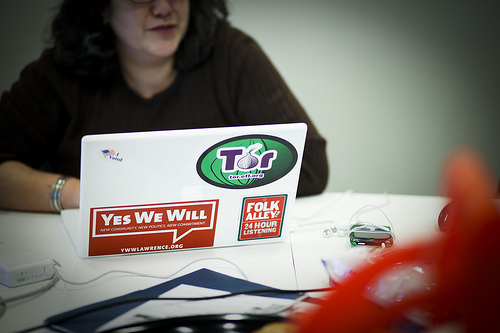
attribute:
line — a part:
[235, 197, 246, 241]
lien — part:
[341, 195, 397, 221]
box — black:
[349, 229, 393, 247]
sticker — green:
[197, 134, 299, 189]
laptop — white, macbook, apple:
[62, 121, 309, 259]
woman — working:
[0, 0, 332, 213]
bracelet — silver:
[49, 173, 69, 216]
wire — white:
[238, 294, 311, 314]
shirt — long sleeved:
[0, 17, 330, 197]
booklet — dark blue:
[43, 268, 306, 332]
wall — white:
[226, 1, 498, 195]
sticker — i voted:
[101, 149, 123, 162]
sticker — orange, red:
[86, 200, 219, 257]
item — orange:
[288, 146, 498, 332]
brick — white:
[2, 248, 55, 289]